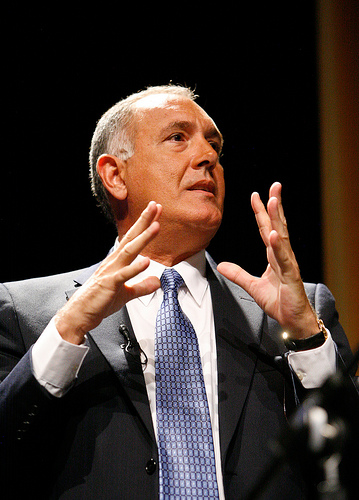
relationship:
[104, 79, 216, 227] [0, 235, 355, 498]
man wearing coat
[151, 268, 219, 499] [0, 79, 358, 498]
blue tie on man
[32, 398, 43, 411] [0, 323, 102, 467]
button on man's arm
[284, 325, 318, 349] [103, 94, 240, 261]
watch on man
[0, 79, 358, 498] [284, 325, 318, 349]
man wearing watch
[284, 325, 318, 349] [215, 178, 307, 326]
watch on left hand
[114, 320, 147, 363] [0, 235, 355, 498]
mic clipped in coat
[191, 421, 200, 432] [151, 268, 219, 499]
squares on blue tie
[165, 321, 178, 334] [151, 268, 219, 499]
squares on blue tie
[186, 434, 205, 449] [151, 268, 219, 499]
squares on blue tie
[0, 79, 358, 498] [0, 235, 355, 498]
man in a coat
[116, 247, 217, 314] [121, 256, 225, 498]
collar of a white shirt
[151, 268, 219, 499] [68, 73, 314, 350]
blue tie around man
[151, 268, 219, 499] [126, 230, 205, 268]
blue tie around neck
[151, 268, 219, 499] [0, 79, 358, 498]
blue tie around a man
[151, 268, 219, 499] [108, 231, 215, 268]
blue tie around a neck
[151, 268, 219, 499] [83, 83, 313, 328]
blue tie around a man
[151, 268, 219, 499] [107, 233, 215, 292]
blue tie around a neck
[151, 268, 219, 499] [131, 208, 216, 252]
blue tie around a man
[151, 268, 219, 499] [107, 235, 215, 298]
blue tie around a neck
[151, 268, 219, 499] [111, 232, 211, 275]
blue tie around a neck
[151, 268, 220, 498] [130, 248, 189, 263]
blue tie around a neck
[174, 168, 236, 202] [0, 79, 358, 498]
mouth of a man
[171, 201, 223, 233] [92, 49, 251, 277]
chin of a man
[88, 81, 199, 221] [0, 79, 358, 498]
hair of a man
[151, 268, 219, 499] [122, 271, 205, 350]
blue tie with no dimple in knot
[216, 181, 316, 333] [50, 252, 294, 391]
hand being used in a gesture